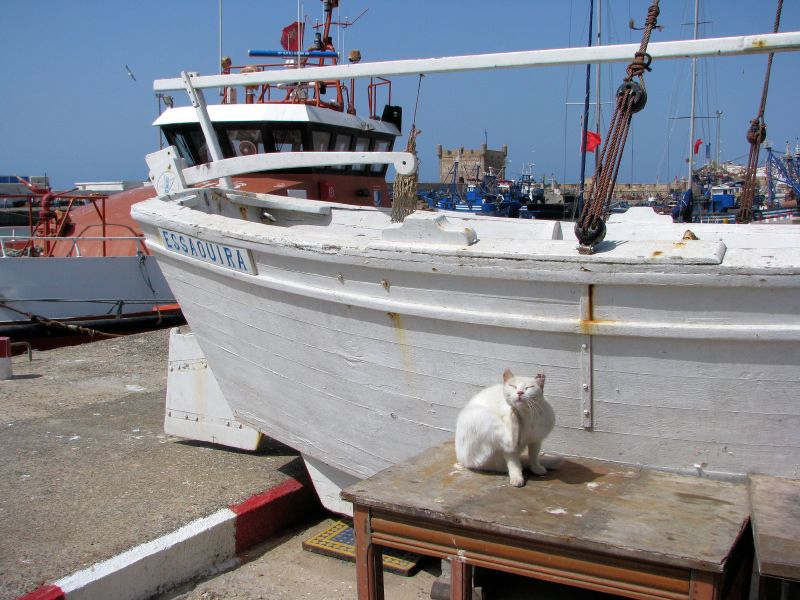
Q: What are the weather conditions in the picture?
A: It is clear.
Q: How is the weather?
A: It is clear.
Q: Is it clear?
A: Yes, it is clear.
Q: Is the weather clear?
A: Yes, it is clear.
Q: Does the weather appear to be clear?
A: Yes, it is clear.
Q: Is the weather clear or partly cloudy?
A: It is clear.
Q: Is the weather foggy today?
A: No, it is clear.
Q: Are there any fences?
A: No, there are no fences.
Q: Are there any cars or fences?
A: No, there are no fences or cars.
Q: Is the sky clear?
A: Yes, the sky is clear.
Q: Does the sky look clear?
A: Yes, the sky is clear.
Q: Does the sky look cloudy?
A: No, the sky is clear.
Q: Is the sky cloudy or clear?
A: The sky is clear.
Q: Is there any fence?
A: No, there are no fences.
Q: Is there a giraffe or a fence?
A: No, there are no fences or giraffes.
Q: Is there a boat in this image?
A: Yes, there is a boat.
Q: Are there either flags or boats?
A: Yes, there is a boat.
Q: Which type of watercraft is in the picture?
A: The watercraft is a boat.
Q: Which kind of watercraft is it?
A: The watercraft is a boat.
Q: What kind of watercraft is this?
A: This is a boat.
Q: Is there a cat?
A: Yes, there is a cat.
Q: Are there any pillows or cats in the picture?
A: Yes, there is a cat.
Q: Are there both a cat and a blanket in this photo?
A: No, there is a cat but no blankets.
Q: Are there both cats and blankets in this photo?
A: No, there is a cat but no blankets.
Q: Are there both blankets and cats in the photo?
A: No, there is a cat but no blankets.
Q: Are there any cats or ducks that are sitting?
A: Yes, the cat is sitting.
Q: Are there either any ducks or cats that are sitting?
A: Yes, the cat is sitting.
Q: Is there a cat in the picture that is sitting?
A: Yes, there is a cat that is sitting.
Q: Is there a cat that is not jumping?
A: Yes, there is a cat that is sitting.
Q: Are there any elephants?
A: No, there are no elephants.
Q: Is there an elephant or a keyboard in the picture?
A: No, there are no elephants or keyboards.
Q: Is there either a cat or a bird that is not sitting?
A: No, there is a cat but it is sitting.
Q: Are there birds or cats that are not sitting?
A: No, there is a cat but it is sitting.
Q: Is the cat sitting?
A: Yes, the cat is sitting.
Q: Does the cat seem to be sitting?
A: Yes, the cat is sitting.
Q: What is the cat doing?
A: The cat is sitting.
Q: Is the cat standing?
A: No, the cat is sitting.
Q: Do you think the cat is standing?
A: No, the cat is sitting.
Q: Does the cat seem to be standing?
A: No, the cat is sitting.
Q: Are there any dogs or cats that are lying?
A: No, there is a cat but it is sitting.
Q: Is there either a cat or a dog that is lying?
A: No, there is a cat but it is sitting.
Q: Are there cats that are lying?
A: No, there is a cat but it is sitting.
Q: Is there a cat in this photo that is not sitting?
A: No, there is a cat but it is sitting.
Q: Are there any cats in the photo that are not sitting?
A: No, there is a cat but it is sitting.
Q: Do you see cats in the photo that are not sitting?
A: No, there is a cat but it is sitting.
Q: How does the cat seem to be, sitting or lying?
A: The cat is sitting.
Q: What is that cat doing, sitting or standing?
A: The cat is sitting.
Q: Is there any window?
A: Yes, there are windows.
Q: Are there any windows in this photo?
A: Yes, there are windows.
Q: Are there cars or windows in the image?
A: Yes, there are windows.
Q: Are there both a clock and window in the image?
A: No, there are windows but no clocks.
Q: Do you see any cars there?
A: No, there are no cars.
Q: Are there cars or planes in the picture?
A: No, there are no cars or planes.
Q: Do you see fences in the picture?
A: No, there are no fences.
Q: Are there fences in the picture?
A: No, there are no fences.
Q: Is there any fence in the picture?
A: No, there are no fences.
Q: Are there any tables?
A: Yes, there is a table.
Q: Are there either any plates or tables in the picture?
A: Yes, there is a table.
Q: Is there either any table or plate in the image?
A: Yes, there is a table.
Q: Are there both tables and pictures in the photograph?
A: No, there is a table but no pictures.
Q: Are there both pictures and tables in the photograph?
A: No, there is a table but no pictures.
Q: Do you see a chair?
A: No, there are no chairs.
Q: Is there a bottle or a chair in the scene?
A: No, there are no chairs or bottles.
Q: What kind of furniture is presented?
A: The furniture is a table.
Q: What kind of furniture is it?
A: The piece of furniture is a table.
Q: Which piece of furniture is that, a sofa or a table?
A: This is a table.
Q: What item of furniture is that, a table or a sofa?
A: This is a table.